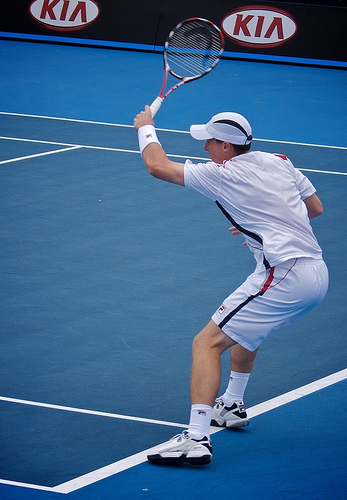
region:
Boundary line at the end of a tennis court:
[41, 334, 344, 494]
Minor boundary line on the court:
[0, 374, 218, 437]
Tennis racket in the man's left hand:
[124, 13, 228, 129]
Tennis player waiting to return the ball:
[123, 6, 339, 496]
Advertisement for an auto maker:
[17, 0, 108, 52]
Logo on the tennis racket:
[181, 24, 214, 66]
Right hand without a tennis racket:
[220, 148, 326, 252]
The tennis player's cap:
[178, 104, 258, 153]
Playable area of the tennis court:
[0, 106, 346, 497]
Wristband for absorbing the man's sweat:
[134, 123, 165, 156]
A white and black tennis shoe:
[145, 429, 211, 464]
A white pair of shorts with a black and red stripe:
[210, 255, 330, 351]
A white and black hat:
[188, 111, 253, 145]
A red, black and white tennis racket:
[148, 17, 224, 116]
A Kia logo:
[220, 6, 298, 50]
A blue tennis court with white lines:
[1, 30, 345, 499]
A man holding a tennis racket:
[133, 17, 329, 466]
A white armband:
[137, 124, 161, 156]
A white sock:
[187, 402, 213, 436]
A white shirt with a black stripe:
[183, 149, 323, 271]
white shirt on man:
[182, 159, 326, 263]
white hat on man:
[185, 110, 255, 142]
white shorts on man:
[218, 259, 327, 349]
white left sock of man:
[180, 399, 212, 433]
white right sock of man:
[224, 368, 242, 402]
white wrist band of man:
[130, 122, 154, 150]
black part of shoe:
[189, 433, 213, 449]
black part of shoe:
[225, 404, 244, 418]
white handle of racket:
[141, 96, 160, 112]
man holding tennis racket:
[127, 16, 330, 470]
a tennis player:
[132, 18, 329, 489]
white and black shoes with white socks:
[148, 370, 249, 468]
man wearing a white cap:
[191, 107, 253, 146]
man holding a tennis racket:
[132, 17, 225, 130]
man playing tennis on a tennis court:
[4, 0, 346, 493]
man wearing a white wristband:
[136, 122, 161, 154]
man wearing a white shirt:
[185, 149, 323, 259]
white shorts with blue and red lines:
[210, 249, 332, 355]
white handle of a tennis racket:
[149, 93, 166, 117]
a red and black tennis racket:
[159, 15, 224, 98]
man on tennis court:
[134, 26, 324, 474]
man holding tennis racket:
[114, 30, 235, 120]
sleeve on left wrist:
[134, 124, 161, 148]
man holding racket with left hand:
[132, 7, 309, 262]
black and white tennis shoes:
[147, 429, 224, 464]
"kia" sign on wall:
[221, 10, 297, 48]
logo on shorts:
[213, 302, 227, 318]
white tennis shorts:
[234, 253, 328, 355]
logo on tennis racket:
[183, 26, 213, 68]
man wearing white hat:
[183, 111, 259, 167]